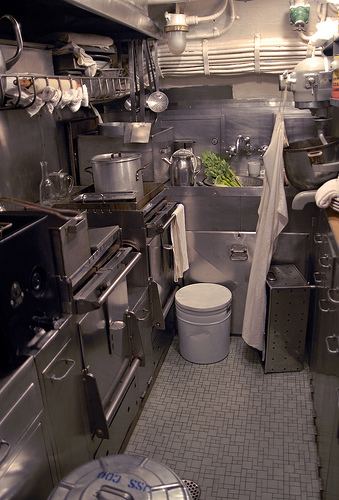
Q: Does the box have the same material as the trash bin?
A: Yes, both the box and the trash bin are made of metal.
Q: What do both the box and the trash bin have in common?
A: The material, both the box and the trash bin are metallic.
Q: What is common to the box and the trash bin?
A: The material, both the box and the trash bin are metallic.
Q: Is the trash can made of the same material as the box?
A: Yes, both the trash can and the box are made of metal.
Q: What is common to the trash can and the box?
A: The material, both the trash can and the box are metallic.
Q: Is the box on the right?
A: Yes, the box is on the right of the image.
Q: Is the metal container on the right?
A: Yes, the box is on the right of the image.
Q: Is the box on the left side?
A: No, the box is on the right of the image.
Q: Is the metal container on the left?
A: No, the box is on the right of the image.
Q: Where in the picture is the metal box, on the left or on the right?
A: The box is on the right of the image.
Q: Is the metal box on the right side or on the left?
A: The box is on the right of the image.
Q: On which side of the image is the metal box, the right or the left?
A: The box is on the right of the image.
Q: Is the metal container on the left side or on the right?
A: The box is on the right of the image.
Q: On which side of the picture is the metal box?
A: The box is on the right of the image.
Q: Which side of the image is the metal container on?
A: The box is on the right of the image.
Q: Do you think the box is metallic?
A: Yes, the box is metallic.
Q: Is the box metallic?
A: Yes, the box is metallic.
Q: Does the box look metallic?
A: Yes, the box is metallic.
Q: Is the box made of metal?
A: Yes, the box is made of metal.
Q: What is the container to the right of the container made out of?
A: The box is made of metal.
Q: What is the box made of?
A: The box is made of metal.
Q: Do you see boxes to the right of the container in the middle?
A: Yes, there is a box to the right of the container.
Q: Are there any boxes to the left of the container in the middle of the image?
A: No, the box is to the right of the container.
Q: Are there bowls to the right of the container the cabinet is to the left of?
A: No, there is a box to the right of the container.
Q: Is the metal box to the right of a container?
A: Yes, the box is to the right of a container.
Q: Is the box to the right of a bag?
A: No, the box is to the right of a container.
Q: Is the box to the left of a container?
A: No, the box is to the right of a container.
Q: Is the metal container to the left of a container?
A: No, the box is to the right of a container.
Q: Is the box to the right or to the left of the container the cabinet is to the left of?
A: The box is to the right of the container.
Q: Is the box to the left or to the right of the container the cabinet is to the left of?
A: The box is to the right of the container.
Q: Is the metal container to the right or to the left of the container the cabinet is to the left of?
A: The box is to the right of the container.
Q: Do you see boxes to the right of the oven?
A: Yes, there is a box to the right of the oven.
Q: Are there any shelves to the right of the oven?
A: No, there is a box to the right of the oven.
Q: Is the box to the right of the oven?
A: Yes, the box is to the right of the oven.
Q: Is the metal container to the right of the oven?
A: Yes, the box is to the right of the oven.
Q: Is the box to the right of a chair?
A: No, the box is to the right of the oven.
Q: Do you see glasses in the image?
A: No, there are no glasses.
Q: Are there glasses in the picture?
A: No, there are no glasses.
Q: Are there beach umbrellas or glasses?
A: No, there are no glasses or beach umbrellas.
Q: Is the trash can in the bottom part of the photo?
A: Yes, the trash can is in the bottom of the image.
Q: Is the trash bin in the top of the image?
A: No, the trash bin is in the bottom of the image.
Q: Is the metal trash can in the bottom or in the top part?
A: The garbage bin is in the bottom of the image.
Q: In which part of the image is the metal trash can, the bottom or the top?
A: The garbage bin is in the bottom of the image.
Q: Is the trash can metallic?
A: Yes, the trash can is metallic.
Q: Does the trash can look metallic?
A: Yes, the trash can is metallic.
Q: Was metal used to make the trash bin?
A: Yes, the trash bin is made of metal.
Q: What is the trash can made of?
A: The garbage bin is made of metal.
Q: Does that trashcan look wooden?
A: No, the trashcan is metallic.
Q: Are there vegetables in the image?
A: Yes, there are vegetables.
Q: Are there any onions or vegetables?
A: Yes, there are vegetables.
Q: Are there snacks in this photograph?
A: No, there are no snacks.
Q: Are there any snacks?
A: No, there are no snacks.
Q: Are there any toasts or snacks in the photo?
A: No, there are no snacks or toasts.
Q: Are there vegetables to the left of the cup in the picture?
A: Yes, there are vegetables to the left of the cup.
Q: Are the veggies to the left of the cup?
A: Yes, the veggies are to the left of the cup.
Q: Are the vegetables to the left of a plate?
A: No, the vegetables are to the left of the cup.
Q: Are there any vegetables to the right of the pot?
A: Yes, there are vegetables to the right of the pot.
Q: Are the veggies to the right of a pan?
A: No, the veggies are to the right of the pot.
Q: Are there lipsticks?
A: No, there are no lipsticks.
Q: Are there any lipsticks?
A: No, there are no lipsticks.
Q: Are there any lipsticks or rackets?
A: No, there are no lipsticks or rackets.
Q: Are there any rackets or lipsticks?
A: No, there are no lipsticks or rackets.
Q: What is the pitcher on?
A: The pitcher is on the counter.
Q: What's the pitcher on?
A: The pitcher is on the counter.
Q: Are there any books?
A: No, there are no books.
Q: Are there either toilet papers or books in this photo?
A: No, there are no books or toilet papers.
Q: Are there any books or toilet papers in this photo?
A: No, there are no books or toilet papers.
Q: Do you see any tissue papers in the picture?
A: No, there are no tissue papers.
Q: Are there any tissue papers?
A: No, there are no tissue papers.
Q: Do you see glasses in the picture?
A: No, there are no glasses.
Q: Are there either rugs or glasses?
A: No, there are no glasses or rugs.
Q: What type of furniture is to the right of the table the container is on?
A: The pieces of furniture are cabinets.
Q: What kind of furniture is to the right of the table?
A: The pieces of furniture are cabinets.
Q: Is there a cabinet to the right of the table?
A: Yes, there are cabinets to the right of the table.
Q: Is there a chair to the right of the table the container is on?
A: No, there are cabinets to the right of the table.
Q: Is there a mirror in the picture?
A: No, there are no mirrors.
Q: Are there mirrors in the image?
A: No, there are no mirrors.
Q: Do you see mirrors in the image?
A: No, there are no mirrors.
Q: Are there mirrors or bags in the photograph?
A: No, there are no mirrors or bags.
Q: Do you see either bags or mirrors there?
A: No, there are no mirrors or bags.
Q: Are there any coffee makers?
A: No, there are no coffee makers.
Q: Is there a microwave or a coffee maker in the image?
A: No, there are no coffee makers or microwaves.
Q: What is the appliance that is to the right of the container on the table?
A: The appliance is a stove.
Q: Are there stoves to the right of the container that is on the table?
A: Yes, there is a stove to the right of the container.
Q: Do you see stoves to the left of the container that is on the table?
A: No, the stove is to the right of the container.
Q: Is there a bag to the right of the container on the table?
A: No, there is a stove to the right of the container.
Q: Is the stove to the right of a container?
A: Yes, the stove is to the right of a container.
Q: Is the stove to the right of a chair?
A: No, the stove is to the right of a container.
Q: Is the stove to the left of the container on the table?
A: No, the stove is to the right of the container.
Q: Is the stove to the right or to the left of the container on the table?
A: The stove is to the right of the container.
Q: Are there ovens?
A: Yes, there is an oven.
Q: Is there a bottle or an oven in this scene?
A: Yes, there is an oven.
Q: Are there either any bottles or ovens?
A: Yes, there is an oven.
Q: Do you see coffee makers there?
A: No, there are no coffee makers.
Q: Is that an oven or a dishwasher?
A: That is an oven.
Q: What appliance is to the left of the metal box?
A: The appliance is an oven.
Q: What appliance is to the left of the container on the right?
A: The appliance is an oven.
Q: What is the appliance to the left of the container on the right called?
A: The appliance is an oven.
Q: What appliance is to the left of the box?
A: The appliance is an oven.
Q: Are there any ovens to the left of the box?
A: Yes, there is an oven to the left of the box.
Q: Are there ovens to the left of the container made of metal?
A: Yes, there is an oven to the left of the box.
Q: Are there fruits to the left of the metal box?
A: No, there is an oven to the left of the box.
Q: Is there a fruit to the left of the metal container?
A: No, there is an oven to the left of the box.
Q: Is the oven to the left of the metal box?
A: Yes, the oven is to the left of the box.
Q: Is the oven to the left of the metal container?
A: Yes, the oven is to the left of the box.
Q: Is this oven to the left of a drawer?
A: No, the oven is to the left of the box.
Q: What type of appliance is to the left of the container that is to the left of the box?
A: The appliance is an oven.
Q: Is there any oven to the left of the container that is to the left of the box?
A: Yes, there is an oven to the left of the container.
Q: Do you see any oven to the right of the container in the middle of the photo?
A: No, the oven is to the left of the container.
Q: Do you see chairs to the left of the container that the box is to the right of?
A: No, there is an oven to the left of the container.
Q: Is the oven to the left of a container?
A: Yes, the oven is to the left of a container.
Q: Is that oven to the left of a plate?
A: No, the oven is to the left of a container.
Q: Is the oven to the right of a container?
A: No, the oven is to the left of a container.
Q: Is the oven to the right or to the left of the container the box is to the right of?
A: The oven is to the left of the container.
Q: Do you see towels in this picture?
A: Yes, there is a towel.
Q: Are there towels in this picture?
A: Yes, there is a towel.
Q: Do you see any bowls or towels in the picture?
A: Yes, there is a towel.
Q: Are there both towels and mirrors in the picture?
A: No, there is a towel but no mirrors.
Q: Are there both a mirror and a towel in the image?
A: No, there is a towel but no mirrors.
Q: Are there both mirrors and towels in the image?
A: No, there is a towel but no mirrors.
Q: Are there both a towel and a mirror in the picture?
A: No, there is a towel but no mirrors.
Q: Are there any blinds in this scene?
A: No, there are no blinds.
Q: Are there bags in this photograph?
A: No, there are no bags.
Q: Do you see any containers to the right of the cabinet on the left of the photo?
A: Yes, there is a container to the right of the cabinet.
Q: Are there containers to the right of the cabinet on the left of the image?
A: Yes, there is a container to the right of the cabinet.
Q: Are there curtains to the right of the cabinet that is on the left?
A: No, there is a container to the right of the cabinet.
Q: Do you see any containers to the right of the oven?
A: Yes, there is a container to the right of the oven.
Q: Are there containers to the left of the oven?
A: No, the container is to the right of the oven.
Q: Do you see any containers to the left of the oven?
A: No, the container is to the right of the oven.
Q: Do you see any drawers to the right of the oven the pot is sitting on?
A: No, there is a container to the right of the oven.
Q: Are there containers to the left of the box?
A: Yes, there is a container to the left of the box.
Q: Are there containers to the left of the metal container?
A: Yes, there is a container to the left of the box.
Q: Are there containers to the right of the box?
A: No, the container is to the left of the box.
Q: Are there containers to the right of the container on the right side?
A: No, the container is to the left of the box.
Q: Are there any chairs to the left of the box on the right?
A: No, there is a container to the left of the box.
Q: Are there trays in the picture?
A: No, there are no trays.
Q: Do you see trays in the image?
A: No, there are no trays.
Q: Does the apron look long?
A: Yes, the apron is long.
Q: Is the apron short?
A: No, the apron is long.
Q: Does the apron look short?
A: No, the apron is long.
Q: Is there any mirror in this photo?
A: No, there are no mirrors.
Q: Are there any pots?
A: Yes, there is a pot.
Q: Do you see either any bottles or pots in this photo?
A: Yes, there is a pot.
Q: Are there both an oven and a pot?
A: Yes, there are both a pot and an oven.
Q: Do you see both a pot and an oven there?
A: Yes, there are both a pot and an oven.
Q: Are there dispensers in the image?
A: No, there are no dispensers.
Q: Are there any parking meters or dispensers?
A: No, there are no dispensers or parking meters.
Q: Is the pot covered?
A: Yes, the pot is covered.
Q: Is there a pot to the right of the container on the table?
A: Yes, there is a pot to the right of the container.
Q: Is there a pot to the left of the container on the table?
A: No, the pot is to the right of the container.